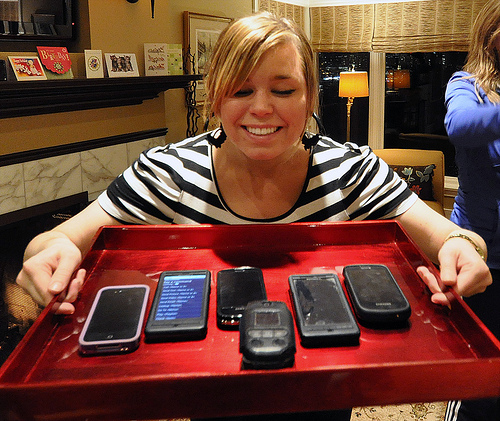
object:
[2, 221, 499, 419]
tray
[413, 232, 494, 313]
hand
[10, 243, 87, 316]
right hand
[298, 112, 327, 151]
earring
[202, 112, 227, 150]
earring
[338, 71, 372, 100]
shade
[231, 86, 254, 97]
eye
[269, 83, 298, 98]
eye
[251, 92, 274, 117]
nose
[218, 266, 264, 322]
phone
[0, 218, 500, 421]
display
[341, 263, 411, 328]
phone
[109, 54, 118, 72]
animals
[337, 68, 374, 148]
lamp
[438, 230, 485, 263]
watch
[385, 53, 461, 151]
window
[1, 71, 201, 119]
mantle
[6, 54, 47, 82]
cards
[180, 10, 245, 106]
picture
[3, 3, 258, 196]
wall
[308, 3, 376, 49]
blinds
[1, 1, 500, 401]
room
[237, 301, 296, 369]
cell phones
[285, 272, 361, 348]
phone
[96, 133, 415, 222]
shirt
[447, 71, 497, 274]
shirt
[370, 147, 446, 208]
chair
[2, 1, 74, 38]
mirror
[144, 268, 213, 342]
phone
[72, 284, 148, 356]
phone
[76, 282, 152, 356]
iphone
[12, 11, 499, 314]
lady